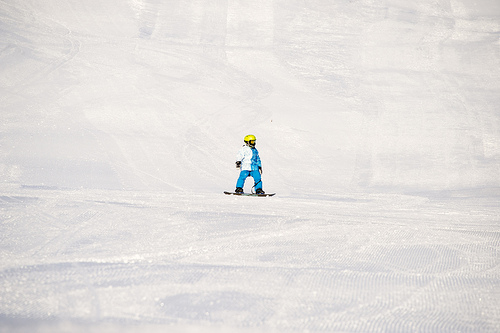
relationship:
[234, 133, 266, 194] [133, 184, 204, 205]
man snowboarding in snow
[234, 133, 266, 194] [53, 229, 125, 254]
man snowboarding in snow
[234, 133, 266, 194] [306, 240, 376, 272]
man snowboarding in snow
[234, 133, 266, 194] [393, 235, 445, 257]
man snowboarding in snow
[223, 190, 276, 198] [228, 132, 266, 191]
snowboard under a man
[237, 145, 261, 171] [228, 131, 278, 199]
white jacket on snowboarder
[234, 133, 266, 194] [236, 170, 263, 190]
man wearing pants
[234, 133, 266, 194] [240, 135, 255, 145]
man wearing helmet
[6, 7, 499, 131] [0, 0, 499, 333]
snow on hill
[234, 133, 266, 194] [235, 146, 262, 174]
man wearing jacket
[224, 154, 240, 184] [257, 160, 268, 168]
glove on right hand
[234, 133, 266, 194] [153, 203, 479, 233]
man snowboarding down hill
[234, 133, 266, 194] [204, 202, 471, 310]
man resting at bottom of snow hill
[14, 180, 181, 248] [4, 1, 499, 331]
bottom of snow hill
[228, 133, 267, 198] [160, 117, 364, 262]
snow boarder in snow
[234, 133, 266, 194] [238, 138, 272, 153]
man wearing a helmet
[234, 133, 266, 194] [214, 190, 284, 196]
man on a snowboard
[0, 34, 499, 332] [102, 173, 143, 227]
snow in background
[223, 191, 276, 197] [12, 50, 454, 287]
snowboard in middle of a snow field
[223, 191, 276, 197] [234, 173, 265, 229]
snowboard wearing pants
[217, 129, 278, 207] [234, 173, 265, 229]
white clouds wearing pants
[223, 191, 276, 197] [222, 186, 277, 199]
snowboard strapped to snowboard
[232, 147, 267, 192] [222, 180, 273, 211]
snowboarder wearing snowboard shoes